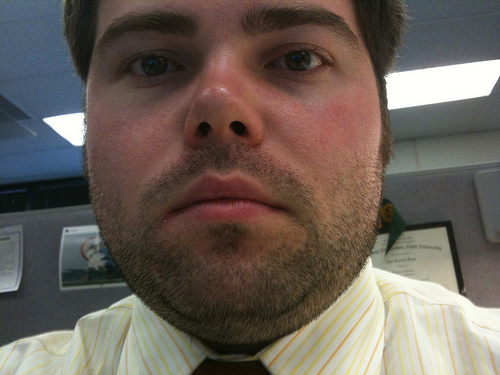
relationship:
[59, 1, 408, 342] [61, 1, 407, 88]
man has hair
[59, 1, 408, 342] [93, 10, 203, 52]
man has eyebrow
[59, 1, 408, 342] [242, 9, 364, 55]
man has eyebrow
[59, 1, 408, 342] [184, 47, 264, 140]
man has nose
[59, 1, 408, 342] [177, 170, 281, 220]
man has lips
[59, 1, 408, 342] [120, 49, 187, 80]
man has eye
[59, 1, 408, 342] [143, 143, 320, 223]
man has mustache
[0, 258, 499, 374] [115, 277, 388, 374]
shirt has lapel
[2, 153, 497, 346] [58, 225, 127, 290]
wall has picture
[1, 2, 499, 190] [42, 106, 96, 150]
ceiling has light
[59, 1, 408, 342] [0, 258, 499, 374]
man wearing shirt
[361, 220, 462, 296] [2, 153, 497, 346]
certificate hanging on wall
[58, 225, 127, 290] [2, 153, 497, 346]
picture on wall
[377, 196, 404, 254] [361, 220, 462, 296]
pennant above certificate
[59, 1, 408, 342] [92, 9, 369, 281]
man has face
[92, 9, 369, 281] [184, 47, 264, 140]
face has nose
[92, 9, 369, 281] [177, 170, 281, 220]
face has lips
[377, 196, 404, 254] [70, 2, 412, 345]
pennant next to head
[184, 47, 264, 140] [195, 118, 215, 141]
nose has nostril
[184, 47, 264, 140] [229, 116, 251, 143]
nose has nostril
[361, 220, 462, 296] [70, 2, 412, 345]
certificate to right of head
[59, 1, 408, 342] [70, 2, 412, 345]
man has head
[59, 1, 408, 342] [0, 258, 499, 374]
man has shirt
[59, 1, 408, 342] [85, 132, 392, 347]
man has facial hair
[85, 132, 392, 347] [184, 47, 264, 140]
facial hair below nose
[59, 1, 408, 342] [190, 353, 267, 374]
man has tie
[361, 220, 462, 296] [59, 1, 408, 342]
certificate behind man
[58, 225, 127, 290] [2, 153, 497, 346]
picture hanging from wall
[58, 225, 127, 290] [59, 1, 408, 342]
picture behind man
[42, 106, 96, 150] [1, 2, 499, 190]
light hanging from ceiling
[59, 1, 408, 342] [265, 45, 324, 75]
man has eye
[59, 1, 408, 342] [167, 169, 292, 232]
man has mouth